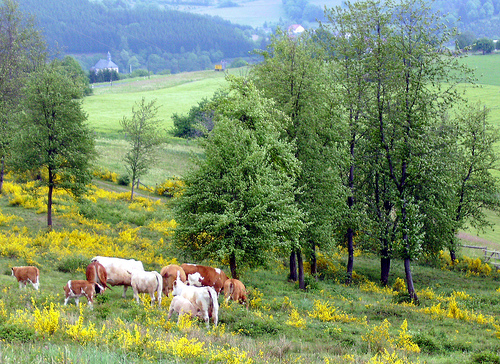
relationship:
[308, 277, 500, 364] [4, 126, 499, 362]
flowers are on hillside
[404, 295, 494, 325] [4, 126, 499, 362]
flowers are on hillside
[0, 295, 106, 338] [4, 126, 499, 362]
flowers are on hillside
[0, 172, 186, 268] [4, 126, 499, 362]
flowers are on hillside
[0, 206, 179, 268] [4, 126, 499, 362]
flowers are on hillside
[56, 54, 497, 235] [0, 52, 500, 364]
hillside covered in grass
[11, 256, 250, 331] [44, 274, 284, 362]
cow standing in grass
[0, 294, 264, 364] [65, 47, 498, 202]
flowers are in field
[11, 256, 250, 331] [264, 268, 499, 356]
cow are in field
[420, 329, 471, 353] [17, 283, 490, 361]
grass on ground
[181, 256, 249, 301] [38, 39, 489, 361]
cow eating in field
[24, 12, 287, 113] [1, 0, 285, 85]
hills and trees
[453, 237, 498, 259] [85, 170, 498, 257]
fence along road